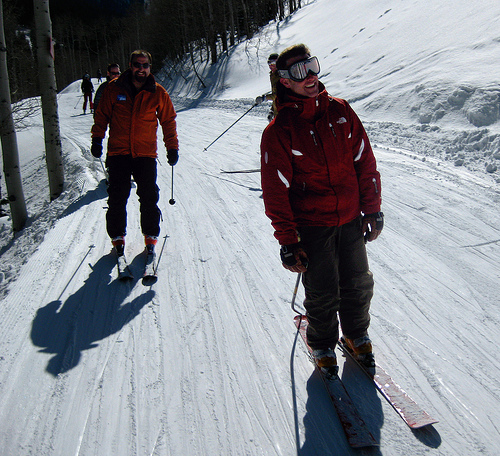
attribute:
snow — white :
[8, 279, 248, 441]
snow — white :
[16, 47, 455, 453]